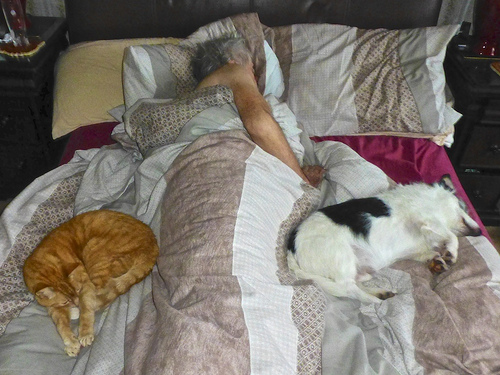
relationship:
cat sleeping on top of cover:
[18, 207, 159, 358] [3, 131, 483, 371]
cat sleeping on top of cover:
[18, 203, 158, 359] [2, 85, 499, 372]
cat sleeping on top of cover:
[18, 207, 159, 358] [167, 143, 278, 373]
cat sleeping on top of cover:
[238, 147, 498, 302] [1, 120, 484, 358]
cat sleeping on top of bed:
[18, 207, 159, 358] [3, 129, 482, 362]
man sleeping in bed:
[152, 31, 322, 375] [377, 136, 439, 174]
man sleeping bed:
[158, 34, 324, 374] [0, 0, 498, 373]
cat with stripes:
[18, 203, 158, 359] [62, 224, 131, 271]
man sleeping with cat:
[152, 31, 322, 375] [18, 203, 158, 359]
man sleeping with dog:
[152, 31, 322, 375] [287, 176, 482, 299]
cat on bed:
[18, 203, 158, 359] [0, 0, 498, 373]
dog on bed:
[287, 176, 482, 299] [0, 0, 498, 373]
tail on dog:
[282, 250, 352, 302] [287, 176, 482, 299]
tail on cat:
[116, 247, 166, 302] [17, 194, 168, 355]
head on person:
[194, 32, 259, 87] [175, 8, 326, 286]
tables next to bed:
[4, 3, 483, 216] [0, 0, 498, 373]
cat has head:
[18, 207, 159, 358] [30, 262, 99, 337]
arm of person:
[193, 29, 327, 187] [229, 68, 327, 192]